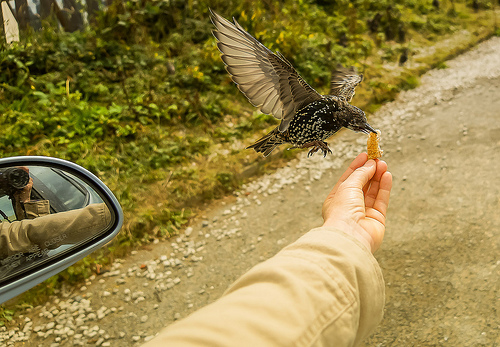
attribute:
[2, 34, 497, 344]
street — grey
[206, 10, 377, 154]
bird — eating, brown, white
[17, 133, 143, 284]
window — reflected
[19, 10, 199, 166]
grass — green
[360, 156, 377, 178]
thumb nail — well groomed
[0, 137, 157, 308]
mirror — silver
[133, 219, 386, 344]
jacket — beige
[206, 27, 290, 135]
wing — brown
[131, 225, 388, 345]
sleeve — khaki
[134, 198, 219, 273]
pebbles — gray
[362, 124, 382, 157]
bread — piece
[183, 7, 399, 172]
bird — flying 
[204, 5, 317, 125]
wings — spread